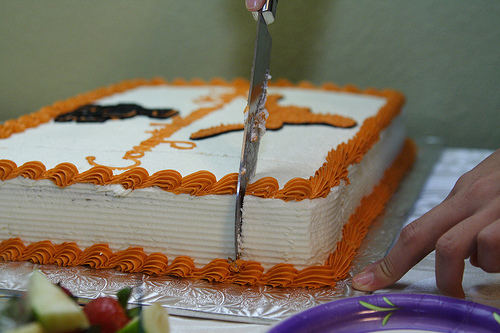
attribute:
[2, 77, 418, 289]
cake — orange, white, rectangular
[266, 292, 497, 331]
plate — purple, paper, round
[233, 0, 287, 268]
knife — silver, cutting, metal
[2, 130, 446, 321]
tray — silver, shiny, held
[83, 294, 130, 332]
fruit — red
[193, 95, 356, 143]
logo — orange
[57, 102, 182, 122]
image — black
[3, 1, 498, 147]
wall — green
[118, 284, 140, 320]
leaf — green